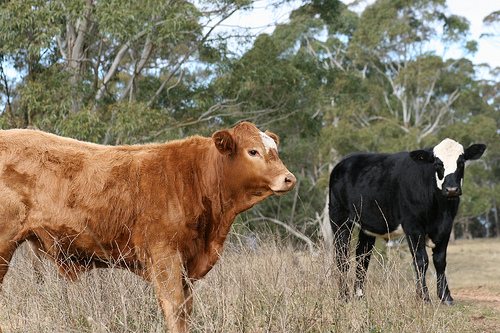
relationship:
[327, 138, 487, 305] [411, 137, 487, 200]
cow has head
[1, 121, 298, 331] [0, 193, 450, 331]
cow inside grass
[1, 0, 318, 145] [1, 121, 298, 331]
tree above cow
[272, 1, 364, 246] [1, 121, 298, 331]
tree above cow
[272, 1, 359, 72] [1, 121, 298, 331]
tree above cow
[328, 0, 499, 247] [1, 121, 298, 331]
tree above cow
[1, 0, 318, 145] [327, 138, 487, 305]
tree above cow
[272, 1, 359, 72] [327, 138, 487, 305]
tree above cow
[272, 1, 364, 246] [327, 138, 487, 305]
tree above cow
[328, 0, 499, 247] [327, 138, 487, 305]
tree above cow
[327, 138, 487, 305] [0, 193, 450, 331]
cow inside grass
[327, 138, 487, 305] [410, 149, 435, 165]
cow has ear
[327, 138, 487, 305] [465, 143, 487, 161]
cow has ear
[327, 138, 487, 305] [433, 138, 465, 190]
cow has patch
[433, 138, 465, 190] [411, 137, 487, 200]
patch on head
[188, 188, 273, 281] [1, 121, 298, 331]
bit hanging from cow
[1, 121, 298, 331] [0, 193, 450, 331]
cow standing in grass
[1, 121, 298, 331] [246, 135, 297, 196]
cow has face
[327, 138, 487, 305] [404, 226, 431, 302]
cow has leg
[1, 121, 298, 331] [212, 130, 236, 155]
cow has ear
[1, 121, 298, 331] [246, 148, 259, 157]
cow has eye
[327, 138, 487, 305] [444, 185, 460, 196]
cow has nose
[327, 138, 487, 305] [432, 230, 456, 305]
cow has leg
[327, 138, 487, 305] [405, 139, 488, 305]
cow has front